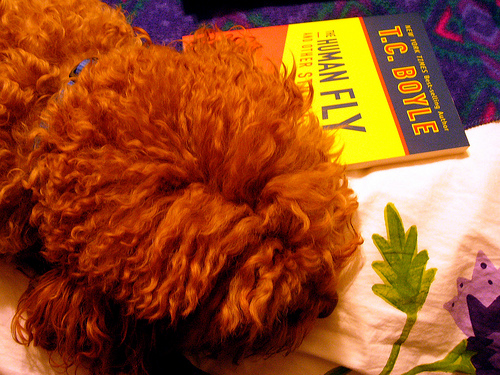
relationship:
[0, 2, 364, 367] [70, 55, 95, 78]
dog wearing collar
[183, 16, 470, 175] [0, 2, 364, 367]
book next to dog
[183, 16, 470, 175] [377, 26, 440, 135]
book by t c boyle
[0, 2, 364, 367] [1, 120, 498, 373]
dog on top of sheet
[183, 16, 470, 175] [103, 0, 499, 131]
book on top of shawl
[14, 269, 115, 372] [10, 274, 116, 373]
ear covered with hair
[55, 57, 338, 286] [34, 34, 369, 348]
top of head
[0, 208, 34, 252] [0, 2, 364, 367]
paw of dog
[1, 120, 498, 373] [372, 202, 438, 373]
sheet with leaf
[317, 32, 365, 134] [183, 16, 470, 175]
title of book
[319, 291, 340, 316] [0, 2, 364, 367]
nose of dog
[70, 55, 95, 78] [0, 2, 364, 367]
collar of dog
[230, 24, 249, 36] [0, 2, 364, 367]
hair of dog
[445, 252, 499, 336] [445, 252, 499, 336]
portion of flower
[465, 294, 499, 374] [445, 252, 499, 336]
portion of flower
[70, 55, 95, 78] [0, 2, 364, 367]
collar on dog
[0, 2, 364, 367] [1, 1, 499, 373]
dog on bed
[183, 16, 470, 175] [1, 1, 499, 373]
book on bed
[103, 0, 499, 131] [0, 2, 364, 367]
shawl under dog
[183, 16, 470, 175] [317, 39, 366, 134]
book says human fly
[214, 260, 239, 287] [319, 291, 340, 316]
eye and nose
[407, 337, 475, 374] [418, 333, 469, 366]
green on white